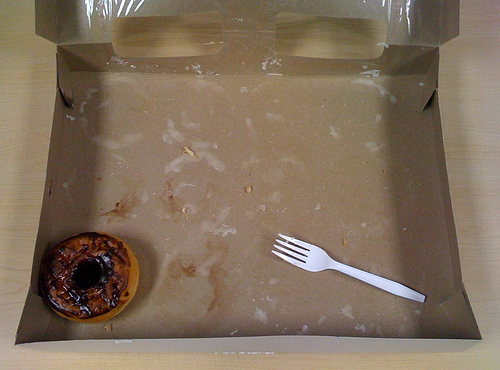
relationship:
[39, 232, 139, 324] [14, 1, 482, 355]
doughnut in box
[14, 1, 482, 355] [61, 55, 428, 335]
box has sugar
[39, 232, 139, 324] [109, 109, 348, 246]
doughnut has crumbs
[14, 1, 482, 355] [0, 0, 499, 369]
box on table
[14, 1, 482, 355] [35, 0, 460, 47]
box has plastic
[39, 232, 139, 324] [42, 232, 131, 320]
doughnut has chocolate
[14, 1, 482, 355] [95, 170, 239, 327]
box has a smear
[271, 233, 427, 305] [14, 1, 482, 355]
fork in box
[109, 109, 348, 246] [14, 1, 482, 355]
crumbs are in box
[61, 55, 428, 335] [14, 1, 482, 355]
sugar in box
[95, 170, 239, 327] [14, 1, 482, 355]
smear in box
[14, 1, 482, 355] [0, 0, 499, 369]
box sitting on table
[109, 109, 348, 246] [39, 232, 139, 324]
crumbs are from doughnut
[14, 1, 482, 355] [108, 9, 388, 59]
box has windows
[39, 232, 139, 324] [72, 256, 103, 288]
doughnut has no center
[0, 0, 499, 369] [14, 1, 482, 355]
table under box